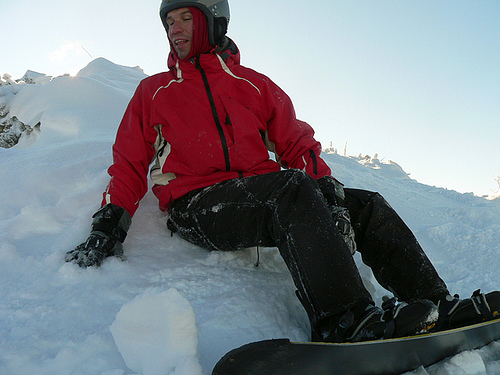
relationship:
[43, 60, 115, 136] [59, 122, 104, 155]
mountain has snow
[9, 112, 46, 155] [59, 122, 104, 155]
rocks have snow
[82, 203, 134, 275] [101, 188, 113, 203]
glove has label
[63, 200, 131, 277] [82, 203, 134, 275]
hand has glove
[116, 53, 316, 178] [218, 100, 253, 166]
jacket has mark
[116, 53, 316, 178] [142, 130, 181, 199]
jacket has cut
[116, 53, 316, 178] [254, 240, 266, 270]
jacket has string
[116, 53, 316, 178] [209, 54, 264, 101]
jacket has line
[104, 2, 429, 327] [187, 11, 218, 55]
man has scarf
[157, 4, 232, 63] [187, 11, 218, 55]
head has scarf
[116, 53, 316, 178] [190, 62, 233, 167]
coat has zipper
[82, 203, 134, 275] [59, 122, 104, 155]
glove has snow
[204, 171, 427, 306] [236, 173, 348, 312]
snowpant has leg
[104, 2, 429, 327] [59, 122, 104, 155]
guy in snow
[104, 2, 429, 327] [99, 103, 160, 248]
person has arm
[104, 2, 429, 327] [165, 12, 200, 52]
person has face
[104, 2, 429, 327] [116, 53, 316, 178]
man has jacket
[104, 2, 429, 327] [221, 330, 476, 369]
man has snowboard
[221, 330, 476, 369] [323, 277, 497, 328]
snowboard on feet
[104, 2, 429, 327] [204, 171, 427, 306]
man has pants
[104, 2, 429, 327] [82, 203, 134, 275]
man has glove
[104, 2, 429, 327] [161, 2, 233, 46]
man has helmet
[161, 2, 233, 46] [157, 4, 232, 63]
helmet on head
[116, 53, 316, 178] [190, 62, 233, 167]
jacket has zipper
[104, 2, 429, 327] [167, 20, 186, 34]
man has nose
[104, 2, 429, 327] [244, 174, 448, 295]
man has legs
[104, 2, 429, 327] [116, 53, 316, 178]
snow boarder has jacket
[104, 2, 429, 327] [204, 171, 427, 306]
snow boarder has pants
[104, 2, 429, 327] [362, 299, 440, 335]
snow boarder has boot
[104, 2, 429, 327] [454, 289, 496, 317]
snow boarder has boot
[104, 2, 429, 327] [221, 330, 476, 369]
snow boarder has snowboard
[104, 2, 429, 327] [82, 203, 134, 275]
snow boarder has glove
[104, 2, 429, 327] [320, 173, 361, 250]
snow boarder has glove